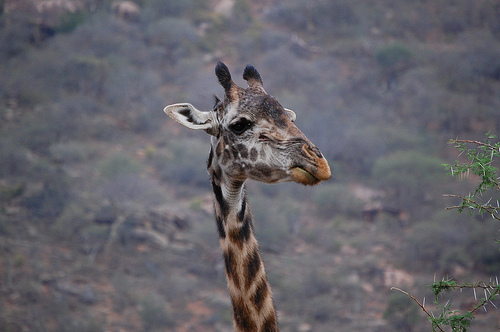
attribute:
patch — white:
[221, 183, 243, 228]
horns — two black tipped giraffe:
[211, 58, 267, 96]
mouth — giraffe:
[283, 154, 336, 191]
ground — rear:
[373, 181, 410, 224]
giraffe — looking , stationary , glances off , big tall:
[163, 62, 332, 329]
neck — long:
[188, 200, 295, 317]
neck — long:
[208, 179, 297, 328]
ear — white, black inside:
[163, 101, 220, 131]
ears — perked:
[163, 102, 210, 130]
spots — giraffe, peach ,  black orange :
[216, 195, 271, 327]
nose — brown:
[293, 140, 335, 190]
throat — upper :
[218, 177, 255, 221]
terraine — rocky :
[96, 6, 343, 87]